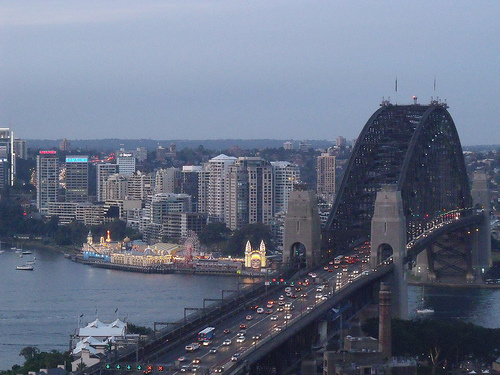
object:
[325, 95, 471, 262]
arch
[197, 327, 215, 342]
bus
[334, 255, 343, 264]
bus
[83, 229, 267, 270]
waterfront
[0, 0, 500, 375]
city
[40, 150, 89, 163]
signs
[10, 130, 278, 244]
buildings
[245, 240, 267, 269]
building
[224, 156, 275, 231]
skyscraper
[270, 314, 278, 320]
vehicle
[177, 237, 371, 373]
cars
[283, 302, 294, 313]
van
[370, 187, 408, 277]
pillar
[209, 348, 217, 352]
car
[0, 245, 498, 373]
river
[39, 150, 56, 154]
red roof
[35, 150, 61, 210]
building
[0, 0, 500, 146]
clouds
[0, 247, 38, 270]
boats/river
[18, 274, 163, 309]
water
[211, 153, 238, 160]
roof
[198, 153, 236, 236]
building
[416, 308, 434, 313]
boat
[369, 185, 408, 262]
stone pillars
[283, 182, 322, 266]
stone pillars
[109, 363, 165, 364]
traffic signals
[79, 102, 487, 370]
bridge